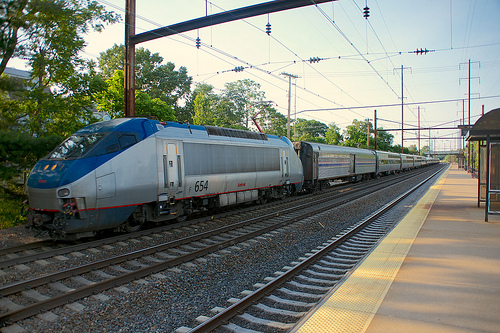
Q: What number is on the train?
A: 654.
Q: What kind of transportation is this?
A: Train.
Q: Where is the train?
A: On the tracks.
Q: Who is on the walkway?
A: Nobody.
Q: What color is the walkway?
A: Brown.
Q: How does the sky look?
A: Light blue.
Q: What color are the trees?
A: Green.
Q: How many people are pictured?
A: 0.